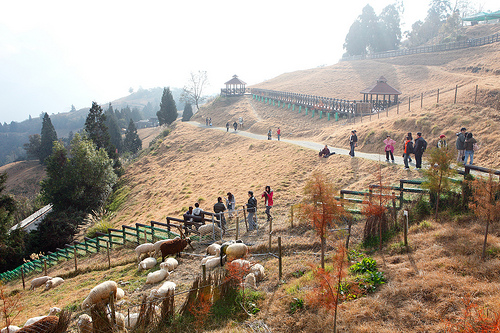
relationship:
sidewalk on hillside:
[175, 115, 498, 180] [0, 25, 498, 327]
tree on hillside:
[181, 99, 198, 123] [0, 25, 498, 327]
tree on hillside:
[153, 85, 178, 127] [0, 25, 498, 327]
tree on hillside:
[121, 117, 142, 155] [0, 25, 498, 327]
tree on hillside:
[37, 107, 58, 167] [0, 25, 498, 327]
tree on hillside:
[344, 0, 376, 65] [0, 25, 498, 327]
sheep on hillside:
[127, 238, 158, 269] [0, 25, 498, 327]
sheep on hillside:
[159, 236, 193, 262] [0, 25, 498, 327]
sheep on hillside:
[154, 249, 177, 272] [0, 25, 498, 327]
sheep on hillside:
[33, 273, 60, 288] [0, 25, 498, 327]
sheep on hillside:
[137, 265, 167, 286] [0, 25, 498, 327]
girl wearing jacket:
[260, 183, 275, 224] [259, 189, 276, 207]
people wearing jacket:
[382, 134, 398, 162] [382, 136, 398, 152]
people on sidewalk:
[382, 134, 398, 162] [175, 115, 498, 180]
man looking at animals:
[241, 189, 257, 231] [2, 215, 270, 329]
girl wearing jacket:
[260, 183, 275, 224] [262, 185, 275, 207]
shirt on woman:
[261, 190, 275, 207] [257, 182, 275, 225]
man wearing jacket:
[241, 189, 257, 231] [245, 196, 259, 216]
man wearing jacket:
[241, 189, 257, 231] [242, 199, 256, 212]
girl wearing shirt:
[260, 183, 275, 224] [379, 139, 399, 155]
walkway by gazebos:
[249, 82, 354, 122] [325, 47, 407, 117]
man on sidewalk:
[241, 189, 257, 231] [175, 115, 498, 180]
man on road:
[241, 189, 257, 231] [218, 96, 458, 175]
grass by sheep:
[335, 237, 447, 327] [83, 249, 234, 303]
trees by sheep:
[275, 250, 368, 330] [137, 250, 277, 320]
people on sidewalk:
[361, 145, 459, 179] [275, 130, 404, 177]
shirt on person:
[249, 189, 291, 223] [240, 180, 300, 242]